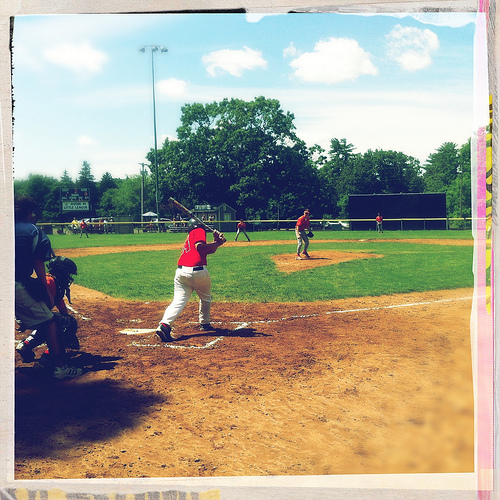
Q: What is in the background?
A: Some trees.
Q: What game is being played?
A: Baseball.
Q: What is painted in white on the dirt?
A: Lines.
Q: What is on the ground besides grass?
A: Dirt.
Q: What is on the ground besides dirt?
A: Grass.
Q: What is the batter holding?
A: Bat.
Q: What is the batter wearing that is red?
A: Jersey.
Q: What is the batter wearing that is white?
A: Pants.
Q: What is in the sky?
A: Clouds.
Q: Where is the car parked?
A: Lot.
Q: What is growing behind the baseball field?
A: Trees.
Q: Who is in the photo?
A: Some people.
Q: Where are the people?
A: On a field.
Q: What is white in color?
A: The line on the field.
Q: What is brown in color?
A: The dirt.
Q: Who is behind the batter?
A: The catcher.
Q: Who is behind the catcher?
A: Umpire.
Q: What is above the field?
A: Clouds.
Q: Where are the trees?
A: Outside the field.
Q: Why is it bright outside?
A: It's daytime.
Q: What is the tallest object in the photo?
A: Light pole.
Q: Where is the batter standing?
A: Batter's box.